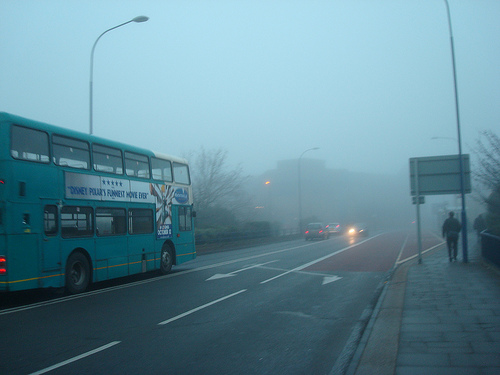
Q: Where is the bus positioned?
A: In the left lane.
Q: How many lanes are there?
A: Three.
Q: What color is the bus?
A: Light blue.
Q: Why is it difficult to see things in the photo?
A: Fog.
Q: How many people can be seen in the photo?
A: Two.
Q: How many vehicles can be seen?
A: Four.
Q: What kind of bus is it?
A: A double-decker.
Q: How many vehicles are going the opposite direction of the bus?
A: One.